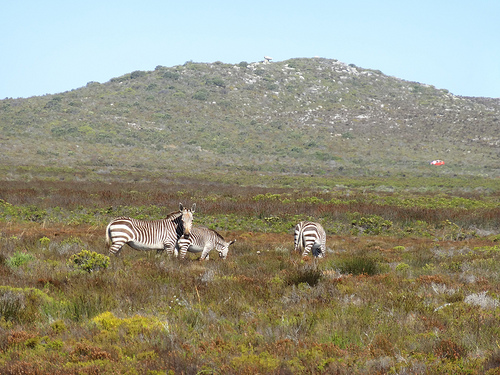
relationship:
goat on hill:
[260, 52, 275, 64] [0, 52, 500, 171]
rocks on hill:
[83, 52, 494, 147] [0, 52, 500, 171]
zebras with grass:
[267, 212, 330, 255] [121, 246, 404, 322]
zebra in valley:
[108, 205, 190, 261] [6, 156, 498, 370]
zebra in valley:
[174, 218, 234, 258] [6, 156, 498, 370]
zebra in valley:
[291, 218, 327, 258] [6, 156, 498, 370]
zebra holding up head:
[99, 209, 199, 270] [175, 204, 205, 244]